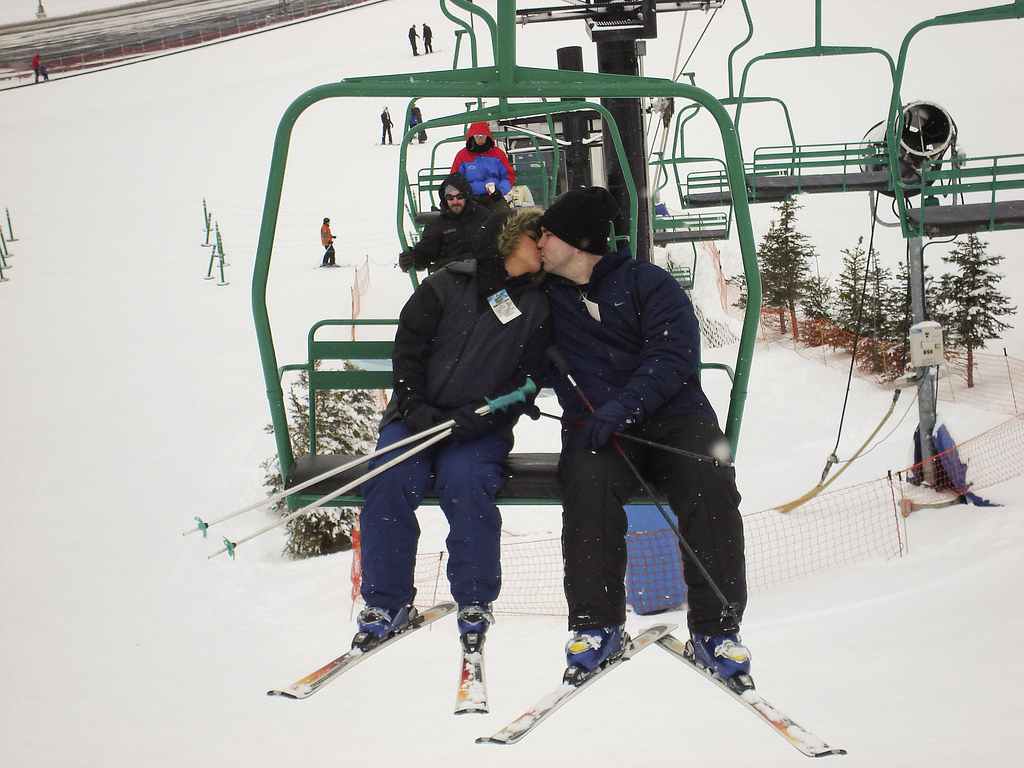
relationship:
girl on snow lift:
[354, 187, 555, 642] [247, 0, 789, 437]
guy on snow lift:
[529, 185, 750, 682] [247, 0, 789, 437]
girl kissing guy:
[354, 187, 555, 642] [529, 185, 750, 682]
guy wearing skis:
[529, 185, 750, 682] [456, 608, 679, 749]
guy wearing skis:
[529, 185, 750, 682] [654, 637, 851, 765]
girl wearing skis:
[354, 187, 555, 642] [266, 589, 476, 701]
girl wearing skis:
[354, 187, 555, 642] [437, 601, 524, 713]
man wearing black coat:
[399, 172, 494, 276] [395, 171, 506, 266]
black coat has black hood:
[395, 171, 506, 266] [436, 171, 472, 213]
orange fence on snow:
[342, 250, 994, 628] [0, 0, 1022, 766]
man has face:
[404, 169, 496, 294] [440, 175, 464, 214]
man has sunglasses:
[404, 169, 496, 294] [440, 187, 469, 204]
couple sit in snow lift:
[250, 186, 850, 764] [247, 0, 789, 437]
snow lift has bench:
[241, 0, 767, 535] [301, 323, 736, 501]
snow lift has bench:
[739, 1, 904, 197] [740, 128, 896, 193]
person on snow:
[290, 205, 383, 260] [251, 205, 384, 355]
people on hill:
[357, 34, 490, 161] [158, 34, 490, 256]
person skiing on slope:
[350, 110, 430, 164] [226, 110, 430, 354]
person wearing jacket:
[432, 132, 521, 216] [432, 132, 521, 216]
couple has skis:
[250, 186, 850, 764] [539, 578, 847, 760]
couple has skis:
[245, 196, 737, 700] [245, 565, 547, 701]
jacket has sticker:
[426, 187, 548, 441] [487, 288, 524, 325]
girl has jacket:
[426, 187, 548, 337] [426, 187, 548, 441]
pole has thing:
[846, 80, 948, 447] [846, 80, 998, 191]